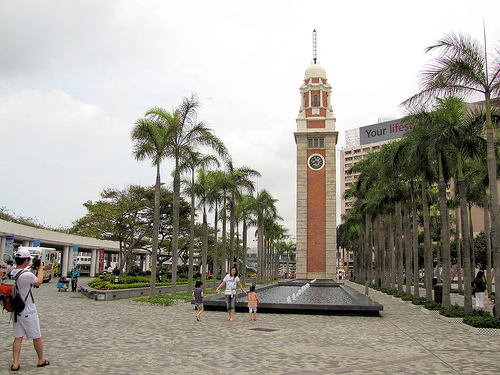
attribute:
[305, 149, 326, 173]
clock — large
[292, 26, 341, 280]
tower — tall, red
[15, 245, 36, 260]
hat — white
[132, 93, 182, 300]
palm tree — tall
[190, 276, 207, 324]
child — walking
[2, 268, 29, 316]
backpack — red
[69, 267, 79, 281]
shirt — blue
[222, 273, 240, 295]
shirt — white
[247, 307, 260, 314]
shorts — white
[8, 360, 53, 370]
sandals — black